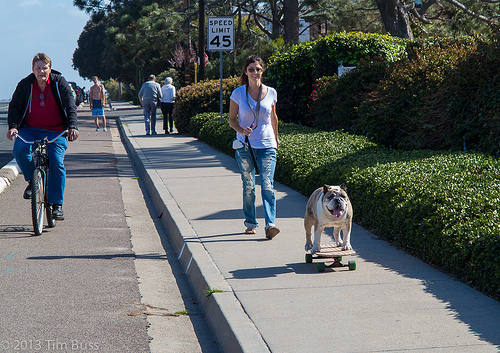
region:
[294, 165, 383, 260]
a dog on a skateboard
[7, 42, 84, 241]
a man riding a bike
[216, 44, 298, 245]
a woman walking on a side walk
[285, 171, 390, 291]
a dog with his tongue hanging out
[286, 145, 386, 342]
a dog riding a skateboard on a sidewalk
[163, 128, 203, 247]
a concrete sidewalk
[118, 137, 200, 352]
a curb next to a road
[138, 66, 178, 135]
two people walking on a side walk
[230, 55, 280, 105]
a woman wearing sun glasses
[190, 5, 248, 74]
a white and black road sign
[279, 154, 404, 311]
a dog on a skateboard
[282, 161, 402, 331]
a dog riding a skateboard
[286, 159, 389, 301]
a dog riding a skateboard on the sidewalk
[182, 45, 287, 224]
a woman smiling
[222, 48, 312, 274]
a woman walking on the sidewalk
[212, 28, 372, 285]
a woman and dog on the sidewalk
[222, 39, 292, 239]
a woman wearing sunglasses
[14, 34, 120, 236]
a man wearing a black jacket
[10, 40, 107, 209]
a man wearing a red shirt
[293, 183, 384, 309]
dog is riding a skateboard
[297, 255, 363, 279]
wheels on the skateboard are green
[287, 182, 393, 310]
skateboard is on the sidewalk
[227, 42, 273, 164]
woman has dog leash around her neck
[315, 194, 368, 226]
dog has his tongue out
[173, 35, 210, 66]
pink flowers on the tree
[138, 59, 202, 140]
couple walking together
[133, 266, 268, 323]
grass in the sidewalk crack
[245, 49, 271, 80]
woman is wearing sunglasses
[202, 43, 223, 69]
STOP sign in to pink flower tree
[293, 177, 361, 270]
Dog riding a skateboard on sidewalk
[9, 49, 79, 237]
Man riding a bicycle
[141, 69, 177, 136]
Elderly couple walking down street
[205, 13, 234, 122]
Speed limit sign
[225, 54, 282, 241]
Woman walking down street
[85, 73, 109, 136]
Man in bike lane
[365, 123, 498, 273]
Green shrubbery along sidewalk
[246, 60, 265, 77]
Sunglasses on woman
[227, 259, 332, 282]
Shadow of skateboarding dog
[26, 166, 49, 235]
Front tire of bike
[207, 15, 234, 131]
rectangular speed limit sign on pole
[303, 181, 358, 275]
bulldog riding skateboard on sidewalk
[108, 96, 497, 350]
long gray cement sidewalk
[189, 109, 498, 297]
green bushes along sidewalk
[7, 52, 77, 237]
man in black shirt riding bicycle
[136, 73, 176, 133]
elderly couple walking on sidewalk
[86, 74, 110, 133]
shirtless young man looking down road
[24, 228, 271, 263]
woman's shadow on the ground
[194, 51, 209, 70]
stop sign showing from behind pole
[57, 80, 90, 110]
line of cars parked by curb